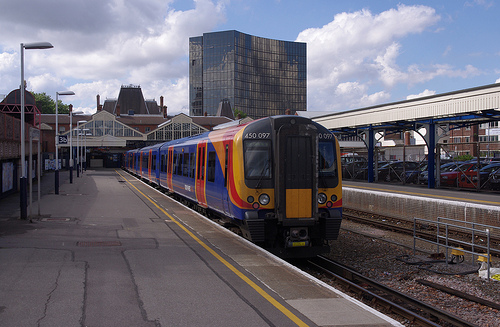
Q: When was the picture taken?
A: In the daytime.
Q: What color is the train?
A: Yellow Red and blue.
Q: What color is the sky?
A: Blue.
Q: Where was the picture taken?
A: At a train station.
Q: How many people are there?
A: None.